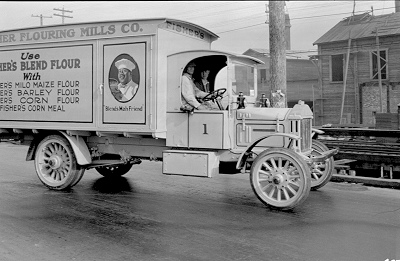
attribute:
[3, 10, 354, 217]
vehicle — old fashioned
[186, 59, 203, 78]
hat — large, white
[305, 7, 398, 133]
building — small, wooden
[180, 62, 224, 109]
man — driving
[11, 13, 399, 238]
picture — black, white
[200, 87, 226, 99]
steering wheel — black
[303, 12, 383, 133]
building — old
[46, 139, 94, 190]
tire — rear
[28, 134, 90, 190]
tires — old style